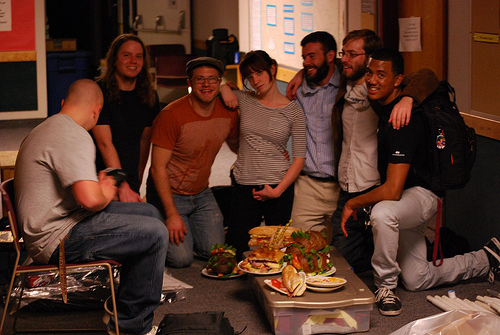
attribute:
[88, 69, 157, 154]
shirt — black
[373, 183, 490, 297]
light jeans — light-colored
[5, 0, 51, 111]
board — bulletin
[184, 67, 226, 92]
glasses — reading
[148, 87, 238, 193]
shirt — gray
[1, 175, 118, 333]
chair — brown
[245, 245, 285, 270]
sandwich — large 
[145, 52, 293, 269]
man — brown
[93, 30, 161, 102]
hair — long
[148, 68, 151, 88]
hair — blonde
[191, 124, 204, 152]
shirt — brown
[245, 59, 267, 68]
hair — brown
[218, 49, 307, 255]
shirt — striped